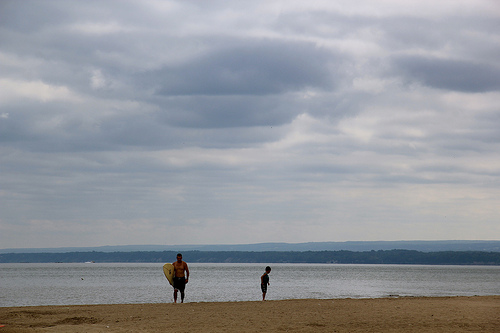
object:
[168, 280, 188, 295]
shorts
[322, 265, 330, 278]
water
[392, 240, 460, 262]
hills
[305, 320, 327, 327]
track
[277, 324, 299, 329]
track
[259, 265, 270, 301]
boy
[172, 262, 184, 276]
without shirt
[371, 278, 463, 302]
beach water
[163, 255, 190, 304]
man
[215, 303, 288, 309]
beach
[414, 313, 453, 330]
beach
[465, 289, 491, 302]
water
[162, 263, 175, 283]
surfboard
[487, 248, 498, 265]
trees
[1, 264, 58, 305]
ocean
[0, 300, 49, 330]
beach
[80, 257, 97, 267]
boat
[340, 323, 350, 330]
sand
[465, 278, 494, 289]
water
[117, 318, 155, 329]
beach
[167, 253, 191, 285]
tank top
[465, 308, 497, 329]
beach